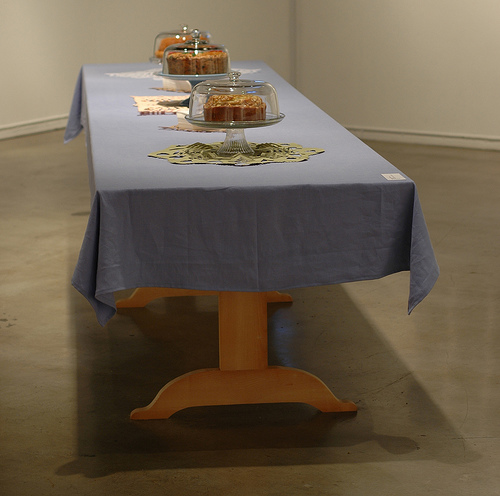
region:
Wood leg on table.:
[127, 287, 360, 426]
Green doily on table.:
[149, 136, 322, 168]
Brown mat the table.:
[135, 91, 194, 118]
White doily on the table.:
[105, 63, 262, 80]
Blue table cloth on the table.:
[60, 43, 452, 331]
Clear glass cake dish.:
[187, 68, 288, 159]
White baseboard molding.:
[341, 120, 498, 153]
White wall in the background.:
[294, 2, 498, 139]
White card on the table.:
[378, 168, 405, 183]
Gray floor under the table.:
[1, 99, 498, 494]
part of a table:
[313, 386, 333, 407]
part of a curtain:
[406, 273, 421, 284]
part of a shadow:
[388, 423, 400, 443]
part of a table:
[229, 333, 233, 343]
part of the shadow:
[108, 379, 135, 418]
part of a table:
[231, 338, 236, 349]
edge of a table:
[218, 188, 229, 193]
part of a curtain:
[409, 244, 418, 259]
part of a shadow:
[379, 391, 395, 418]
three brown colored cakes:
[150, 33, 267, 123]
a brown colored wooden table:
[68, 58, 435, 420]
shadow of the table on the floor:
[53, 240, 484, 487]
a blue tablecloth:
[63, 60, 442, 317]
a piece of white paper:
[378, 170, 406, 182]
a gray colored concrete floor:
[2, 128, 494, 494]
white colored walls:
[0, 0, 499, 141]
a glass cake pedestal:
[185, 68, 284, 158]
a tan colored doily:
[148, 143, 325, 168]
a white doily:
[104, 64, 262, 80]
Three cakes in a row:
[148, 25, 288, 131]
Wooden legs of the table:
[114, 258, 367, 427]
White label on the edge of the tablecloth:
[381, 169, 403, 184]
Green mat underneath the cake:
[143, 134, 326, 168]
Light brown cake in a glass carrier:
[184, 74, 288, 154]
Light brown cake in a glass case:
[162, 33, 232, 84]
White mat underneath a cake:
[132, 93, 204, 115]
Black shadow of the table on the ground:
[67, 245, 475, 476]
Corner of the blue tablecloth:
[408, 183, 446, 323]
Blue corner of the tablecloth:
[70, 195, 112, 325]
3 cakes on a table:
[68, 5, 435, 260]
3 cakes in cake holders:
[58, 7, 431, 357]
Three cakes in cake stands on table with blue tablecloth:
[64, 21, 422, 263]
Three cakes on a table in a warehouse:
[18, 10, 490, 485]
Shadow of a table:
[28, 281, 480, 488]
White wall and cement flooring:
[365, 6, 499, 491]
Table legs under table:
[123, 285, 425, 465]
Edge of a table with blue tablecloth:
[276, 1, 473, 306]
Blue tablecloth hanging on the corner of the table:
[23, 23, 157, 336]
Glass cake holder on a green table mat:
[121, 64, 358, 176]